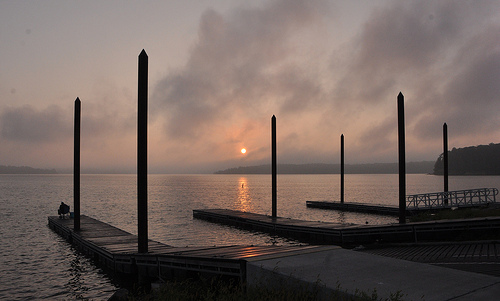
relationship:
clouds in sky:
[152, 0, 332, 147] [8, 6, 494, 177]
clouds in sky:
[152, 0, 332, 147] [76, 7, 156, 46]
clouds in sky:
[154, 5, 312, 133] [8, 6, 494, 177]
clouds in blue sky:
[152, 0, 332, 147] [378, 21, 435, 88]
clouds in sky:
[157, 4, 498, 142] [8, 6, 494, 177]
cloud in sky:
[4, 97, 123, 144] [12, 9, 174, 87]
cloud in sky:
[0, 97, 122, 144] [28, 27, 426, 162]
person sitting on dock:
[58, 201, 71, 219] [48, 209, 498, 299]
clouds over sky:
[152, 0, 332, 147] [8, 6, 494, 177]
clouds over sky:
[288, 95, 310, 115] [8, 6, 494, 177]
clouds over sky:
[410, 27, 500, 150] [8, 6, 494, 177]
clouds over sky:
[329, 1, 476, 117] [8, 6, 494, 177]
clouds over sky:
[459, 58, 488, 103] [8, 6, 494, 177]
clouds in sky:
[181, 3, 399, 89] [11, 8, 483, 136]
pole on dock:
[134, 48, 150, 250] [48, 214, 151, 251]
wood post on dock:
[72, 97, 81, 229] [48, 214, 151, 251]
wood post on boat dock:
[271, 116, 277, 222] [191, 206, 500, 245]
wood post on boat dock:
[397, 93, 405, 223] [191, 206, 500, 245]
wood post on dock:
[339, 134, 344, 202] [305, 194, 394, 214]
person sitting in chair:
[58, 200, 72, 222] [58, 207, 68, 220]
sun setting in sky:
[206, 124, 276, 199] [23, 12, 484, 245]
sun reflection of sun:
[235, 177, 252, 210] [237, 142, 249, 157]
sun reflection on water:
[235, 177, 252, 210] [3, 172, 497, 299]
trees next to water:
[444, 144, 497, 180] [9, 172, 498, 241]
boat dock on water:
[194, 204, 364, 245] [3, 172, 497, 299]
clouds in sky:
[20, 8, 497, 156] [8, 6, 494, 177]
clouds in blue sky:
[152, 0, 332, 147] [0, 0, 494, 171]